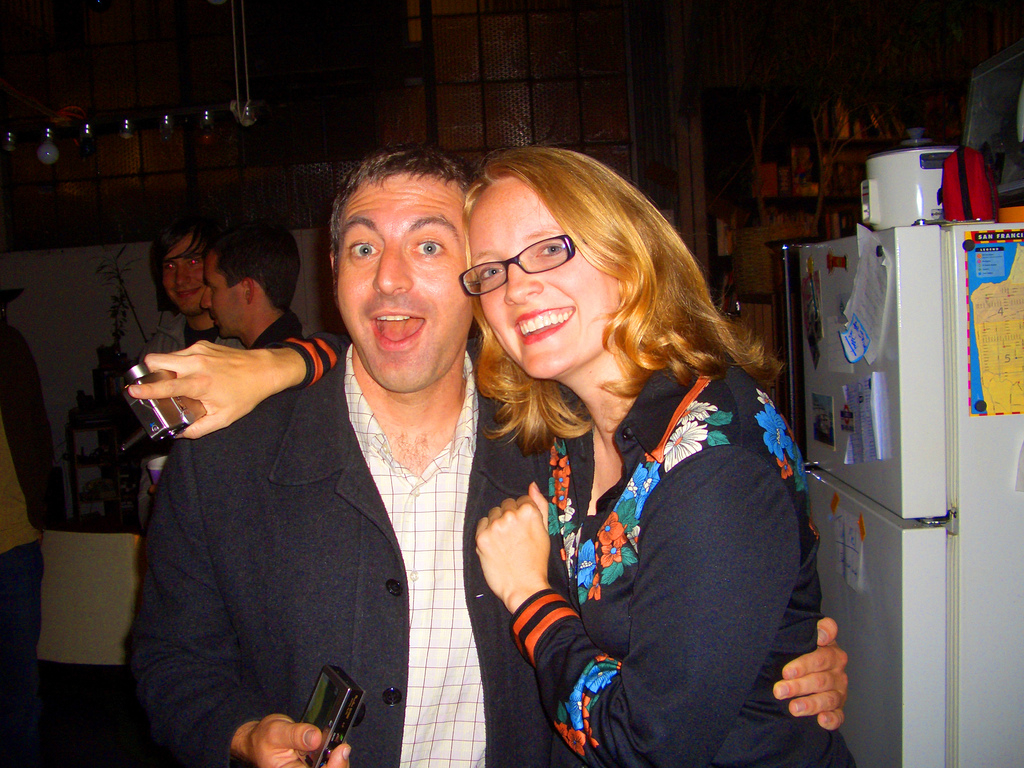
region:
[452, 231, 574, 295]
Glasses on a woman's face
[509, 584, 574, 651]
Orange stripes on a sleeve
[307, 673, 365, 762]
A cell phone in a hand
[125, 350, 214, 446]
A camera in a hand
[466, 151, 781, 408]
Blonde hair on a woman's head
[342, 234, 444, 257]
Blue eyes on a man's face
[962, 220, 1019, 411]
A paper on a refrigerator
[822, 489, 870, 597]
A white paper on a refrigerator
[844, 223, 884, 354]
piece of paper stuck on the fridge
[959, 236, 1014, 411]
piece of paper stuck on the fridge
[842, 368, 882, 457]
piece of paper stuck on the fridge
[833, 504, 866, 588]
piece of paper stuck on the fridge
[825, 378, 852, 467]
piece of paper stuck on the fridge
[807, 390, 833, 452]
piece of paper stuck on the fridge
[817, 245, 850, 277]
piece of paper stuck on the fridge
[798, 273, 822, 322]
piece of paper stuck on the fridge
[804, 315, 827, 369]
piece of paper stuck on the fridge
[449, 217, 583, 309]
A pair of eyeglasses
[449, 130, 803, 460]
Woman has blonde hair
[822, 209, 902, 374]
A white piece of paper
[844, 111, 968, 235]
A white rice cooker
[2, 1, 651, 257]
Brown tiles on the wall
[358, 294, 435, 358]
A mouth is open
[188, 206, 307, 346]
Man has brown hair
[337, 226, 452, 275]
A pair of eyes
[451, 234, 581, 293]
woman wearing reading glasses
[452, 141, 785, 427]
woman with red hair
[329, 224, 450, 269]
man with blue eyes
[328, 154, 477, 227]
man with brown hair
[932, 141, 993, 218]
red bag on top of the refrigerator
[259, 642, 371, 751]
man holding a camera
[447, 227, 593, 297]
The eyeglasses the woman is wearing.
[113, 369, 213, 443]
The pink camera in the woman's hand.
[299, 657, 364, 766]
The camera in the man's hand.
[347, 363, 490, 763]
The square pattern shirt the man is wearing.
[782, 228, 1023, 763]
The refrigerator behind the woman and the man.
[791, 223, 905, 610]
The papers and magnets on the doors of the refrigerator.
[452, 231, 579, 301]
black framed glasses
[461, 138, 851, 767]
a woman with red hair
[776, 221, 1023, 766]
a white two door refrigerator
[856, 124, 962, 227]
a small crock pot with a gray lid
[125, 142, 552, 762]
a man wearing a gray jacket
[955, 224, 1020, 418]
a blue and yellow magnet on the side of the refrigerator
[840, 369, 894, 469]
a white paper hanging on the refrigerator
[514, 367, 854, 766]
a black, blue, and orange shirt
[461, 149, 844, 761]
a woman wearing glasses and smiling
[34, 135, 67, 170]
a round white light bulb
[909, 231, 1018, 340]
a magnet on the fridge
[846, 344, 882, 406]
a magnet on the fridge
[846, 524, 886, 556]
a magnet on the fridge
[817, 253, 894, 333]
a magnet on the fridge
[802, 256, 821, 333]
a magnet on the fridge